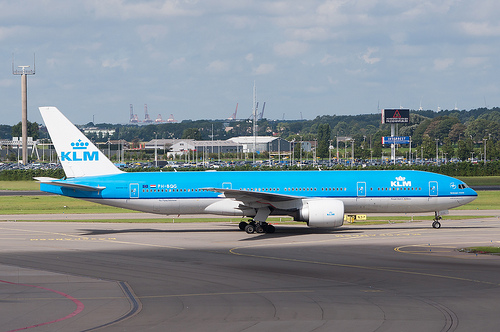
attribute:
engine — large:
[297, 192, 347, 234]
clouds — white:
[1, 1, 498, 126]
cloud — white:
[274, 39, 314, 64]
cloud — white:
[274, 5, 351, 35]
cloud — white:
[445, 17, 497, 42]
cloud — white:
[426, 54, 493, 73]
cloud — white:
[209, 59, 235, 72]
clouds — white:
[89, 9, 244, 90]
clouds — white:
[217, 11, 440, 103]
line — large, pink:
[30, 96, 488, 281]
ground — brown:
[415, 165, 437, 200]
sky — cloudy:
[12, 3, 479, 108]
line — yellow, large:
[228, 242, 498, 292]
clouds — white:
[293, 29, 419, 79]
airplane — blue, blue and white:
[23, 102, 490, 241]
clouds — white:
[455, 18, 494, 40]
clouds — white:
[293, 19, 336, 44]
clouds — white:
[246, 55, 285, 74]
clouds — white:
[141, 39, 173, 62]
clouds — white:
[96, 49, 127, 71]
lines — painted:
[28, 226, 119, 253]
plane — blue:
[23, 100, 479, 231]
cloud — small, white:
[361, 46, 383, 64]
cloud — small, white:
[428, 55, 454, 72]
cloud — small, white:
[251, 58, 281, 76]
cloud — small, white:
[169, 55, 191, 69]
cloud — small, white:
[41, 57, 69, 66]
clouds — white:
[7, 3, 494, 81]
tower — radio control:
[10, 62, 35, 165]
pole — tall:
[19, 68, 28, 175]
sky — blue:
[5, 1, 480, 128]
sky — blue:
[5, 5, 483, 150]